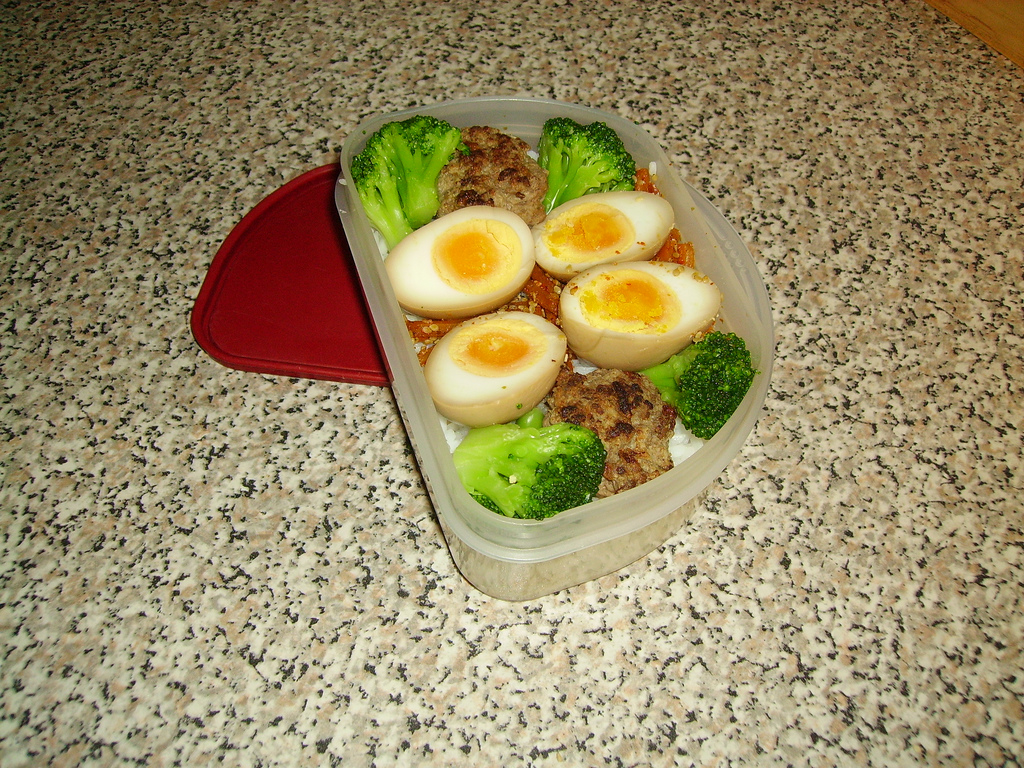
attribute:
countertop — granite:
[60, 454, 465, 731]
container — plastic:
[330, 85, 905, 569]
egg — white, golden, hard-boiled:
[403, 217, 620, 358]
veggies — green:
[498, 374, 687, 563]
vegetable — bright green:
[431, 392, 594, 513]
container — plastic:
[313, 113, 888, 680]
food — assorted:
[375, 150, 710, 496]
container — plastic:
[177, 162, 748, 525]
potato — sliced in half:
[393, 212, 553, 403]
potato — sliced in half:
[538, 188, 696, 364]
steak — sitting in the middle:
[538, 353, 677, 509]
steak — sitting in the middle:
[443, 122, 550, 231]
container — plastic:
[289, 106, 767, 603]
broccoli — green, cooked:
[454, 415, 589, 524]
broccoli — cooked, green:
[542, 119, 629, 217]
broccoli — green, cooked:
[335, 115, 454, 234]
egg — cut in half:
[417, 307, 556, 424]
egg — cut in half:
[369, 219, 536, 308]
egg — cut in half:
[547, 268, 714, 362]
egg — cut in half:
[385, 204, 522, 311]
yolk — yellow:
[437, 223, 507, 288]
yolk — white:
[398, 262, 463, 301]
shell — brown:
[499, 387, 543, 407]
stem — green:
[449, 428, 504, 478]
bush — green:
[538, 426, 584, 509]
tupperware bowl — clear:
[482, 528, 640, 595]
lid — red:
[259, 242, 331, 348]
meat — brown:
[598, 396, 661, 461]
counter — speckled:
[767, 212, 973, 697]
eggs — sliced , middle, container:
[397, 191, 732, 392]